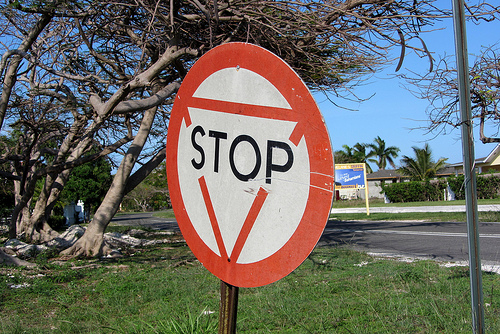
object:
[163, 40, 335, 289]
stop sign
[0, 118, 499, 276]
suburban area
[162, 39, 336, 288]
border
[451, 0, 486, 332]
pole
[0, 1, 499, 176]
sky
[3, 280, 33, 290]
snow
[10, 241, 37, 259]
rocks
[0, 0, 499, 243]
tree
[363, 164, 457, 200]
house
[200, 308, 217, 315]
snow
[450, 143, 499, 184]
dwelling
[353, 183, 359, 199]
pole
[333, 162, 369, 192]
advertisement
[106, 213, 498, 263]
road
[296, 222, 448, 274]
shadows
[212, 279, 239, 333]
pole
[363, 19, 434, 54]
branches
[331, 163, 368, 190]
sign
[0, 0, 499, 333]
background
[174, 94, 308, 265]
triangle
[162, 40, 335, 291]
circle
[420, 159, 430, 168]
leaves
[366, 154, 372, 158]
leaves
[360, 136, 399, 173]
tree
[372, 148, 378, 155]
leaves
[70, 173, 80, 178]
leaves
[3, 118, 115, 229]
tree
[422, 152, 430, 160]
leaves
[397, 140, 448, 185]
tree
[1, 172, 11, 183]
leaves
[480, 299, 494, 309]
patch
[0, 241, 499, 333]
growth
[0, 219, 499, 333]
grass